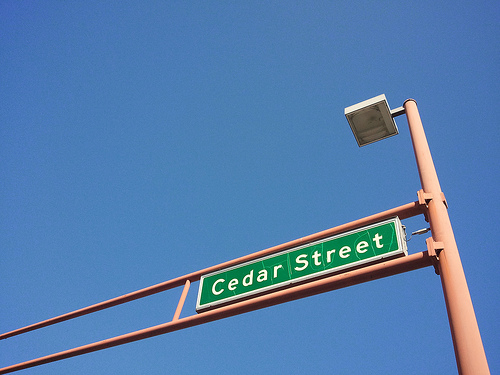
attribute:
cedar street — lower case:
[208, 222, 389, 294]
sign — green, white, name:
[193, 213, 412, 314]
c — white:
[208, 272, 227, 302]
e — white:
[223, 272, 240, 295]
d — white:
[238, 267, 257, 292]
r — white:
[270, 262, 288, 282]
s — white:
[293, 253, 311, 275]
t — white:
[309, 247, 323, 271]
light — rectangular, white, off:
[336, 92, 403, 152]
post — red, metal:
[396, 90, 480, 330]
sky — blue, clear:
[90, 34, 281, 192]